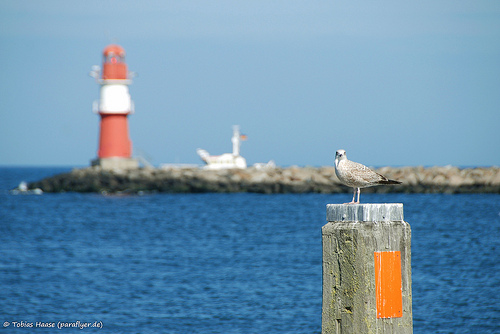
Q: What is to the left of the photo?
A: A red and white lighthouse.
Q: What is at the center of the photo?
A: A boat.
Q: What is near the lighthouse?
A: Large amount of rocks.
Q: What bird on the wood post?
A: Seagull.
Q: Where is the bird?
A: On top of a post.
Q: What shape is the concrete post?
A: Square.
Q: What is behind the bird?
A: Water.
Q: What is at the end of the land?
A: A lighthouse.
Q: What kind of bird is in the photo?
A: A seagull.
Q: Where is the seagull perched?
A: On a piling.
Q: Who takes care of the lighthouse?
A: The Coast Guard.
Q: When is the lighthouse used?
A: On foggy nights.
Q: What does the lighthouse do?
A: Warns ships.